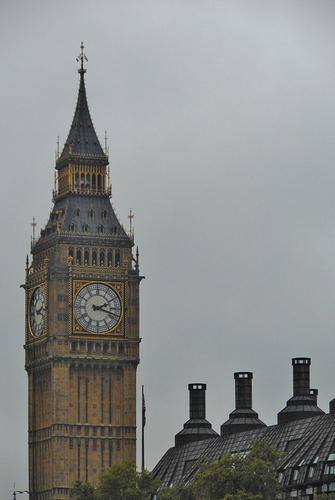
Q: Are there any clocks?
A: Yes, there is a clock.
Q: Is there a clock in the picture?
A: Yes, there is a clock.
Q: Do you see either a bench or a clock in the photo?
A: Yes, there is a clock.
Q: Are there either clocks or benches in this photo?
A: Yes, there is a clock.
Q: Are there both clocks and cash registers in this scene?
A: No, there is a clock but no cash registers.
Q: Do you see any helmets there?
A: No, there are no helmets.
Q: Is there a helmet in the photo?
A: No, there are no helmets.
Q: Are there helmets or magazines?
A: No, there are no helmets or magazines.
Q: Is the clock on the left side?
A: Yes, the clock is on the left of the image.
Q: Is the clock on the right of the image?
A: No, the clock is on the left of the image.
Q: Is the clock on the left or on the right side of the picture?
A: The clock is on the left of the image.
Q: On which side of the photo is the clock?
A: The clock is on the left of the image.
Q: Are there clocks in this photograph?
A: Yes, there is a clock.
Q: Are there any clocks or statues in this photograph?
A: Yes, there is a clock.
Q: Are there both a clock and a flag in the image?
A: Yes, there are both a clock and a flag.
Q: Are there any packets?
A: No, there are no packets.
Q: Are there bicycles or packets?
A: No, there are no packets or bicycles.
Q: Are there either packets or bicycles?
A: No, there are no packets or bicycles.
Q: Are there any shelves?
A: No, there are no shelves.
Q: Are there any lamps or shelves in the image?
A: No, there are no shelves or lamps.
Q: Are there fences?
A: No, there are no fences.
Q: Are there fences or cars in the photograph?
A: No, there are no fences or cars.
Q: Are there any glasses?
A: No, there are no glasses.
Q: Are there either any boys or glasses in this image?
A: No, there are no glasses or boys.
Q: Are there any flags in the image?
A: Yes, there is a flag.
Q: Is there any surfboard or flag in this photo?
A: Yes, there is a flag.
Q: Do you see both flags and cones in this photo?
A: No, there is a flag but no cones.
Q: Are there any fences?
A: No, there are no fences.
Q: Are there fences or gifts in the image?
A: No, there are no fences or gifts.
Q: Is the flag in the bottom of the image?
A: Yes, the flag is in the bottom of the image.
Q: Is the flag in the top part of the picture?
A: No, the flag is in the bottom of the image.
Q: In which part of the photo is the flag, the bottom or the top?
A: The flag is in the bottom of the image.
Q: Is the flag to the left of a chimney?
A: Yes, the flag is to the left of a chimney.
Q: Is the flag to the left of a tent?
A: No, the flag is to the left of a chimney.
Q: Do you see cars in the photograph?
A: No, there are no cars.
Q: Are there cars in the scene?
A: No, there are no cars.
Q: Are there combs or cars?
A: No, there are no cars or combs.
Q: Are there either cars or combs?
A: No, there are no cars or combs.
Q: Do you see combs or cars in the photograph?
A: No, there are no cars or combs.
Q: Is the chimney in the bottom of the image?
A: Yes, the chimney is in the bottom of the image.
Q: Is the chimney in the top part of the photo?
A: No, the chimney is in the bottom of the image.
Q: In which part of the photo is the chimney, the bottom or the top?
A: The chimney is in the bottom of the image.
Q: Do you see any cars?
A: No, there are no cars.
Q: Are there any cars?
A: No, there are no cars.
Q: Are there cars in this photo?
A: No, there are no cars.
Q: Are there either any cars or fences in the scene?
A: No, there are no cars or fences.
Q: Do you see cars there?
A: No, there are no cars.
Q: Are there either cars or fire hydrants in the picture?
A: No, there are no cars or fire hydrants.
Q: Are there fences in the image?
A: No, there are no fences.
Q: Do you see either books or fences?
A: No, there are no fences or books.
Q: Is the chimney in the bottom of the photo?
A: Yes, the chimney is in the bottom of the image.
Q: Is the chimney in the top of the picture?
A: No, the chimney is in the bottom of the image.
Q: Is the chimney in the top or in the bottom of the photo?
A: The chimney is in the bottom of the image.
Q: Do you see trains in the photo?
A: No, there are no trains.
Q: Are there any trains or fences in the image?
A: No, there are no trains or fences.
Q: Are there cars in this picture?
A: No, there are no cars.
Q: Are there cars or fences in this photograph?
A: No, there are no cars or fences.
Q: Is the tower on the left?
A: Yes, the tower is on the left of the image.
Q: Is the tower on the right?
A: No, the tower is on the left of the image.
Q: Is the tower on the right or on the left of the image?
A: The tower is on the left of the image.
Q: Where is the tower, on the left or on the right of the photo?
A: The tower is on the left of the image.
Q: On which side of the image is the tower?
A: The tower is on the left of the image.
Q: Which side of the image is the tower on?
A: The tower is on the left of the image.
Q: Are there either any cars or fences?
A: No, there are no cars or fences.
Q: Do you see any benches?
A: No, there are no benches.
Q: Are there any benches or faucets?
A: No, there are no benches or faucets.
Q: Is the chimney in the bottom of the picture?
A: Yes, the chimney is in the bottom of the image.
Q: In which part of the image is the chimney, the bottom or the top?
A: The chimney is in the bottom of the image.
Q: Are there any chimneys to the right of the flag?
A: Yes, there is a chimney to the right of the flag.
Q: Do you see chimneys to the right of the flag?
A: Yes, there is a chimney to the right of the flag.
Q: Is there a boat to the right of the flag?
A: No, there is a chimney to the right of the flag.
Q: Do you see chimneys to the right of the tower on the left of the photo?
A: Yes, there is a chimney to the right of the tower.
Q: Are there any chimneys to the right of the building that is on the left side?
A: Yes, there is a chimney to the right of the tower.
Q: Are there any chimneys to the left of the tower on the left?
A: No, the chimney is to the right of the tower.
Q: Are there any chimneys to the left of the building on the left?
A: No, the chimney is to the right of the tower.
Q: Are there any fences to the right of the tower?
A: No, there is a chimney to the right of the tower.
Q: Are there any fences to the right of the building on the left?
A: No, there is a chimney to the right of the tower.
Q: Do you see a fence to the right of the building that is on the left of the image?
A: No, there is a chimney to the right of the tower.